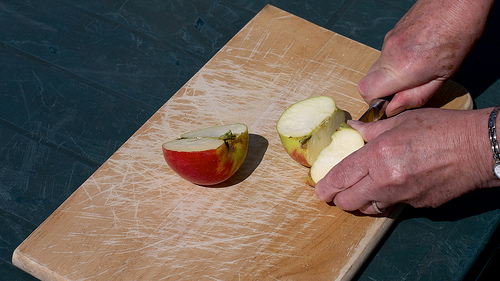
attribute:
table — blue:
[38, 14, 85, 68]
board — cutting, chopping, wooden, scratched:
[231, 31, 298, 136]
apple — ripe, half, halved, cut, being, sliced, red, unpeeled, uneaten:
[181, 106, 244, 173]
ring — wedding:
[366, 202, 410, 231]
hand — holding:
[358, 117, 425, 208]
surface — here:
[293, 81, 329, 121]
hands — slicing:
[340, 44, 451, 185]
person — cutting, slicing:
[361, 24, 426, 106]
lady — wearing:
[376, 46, 464, 196]